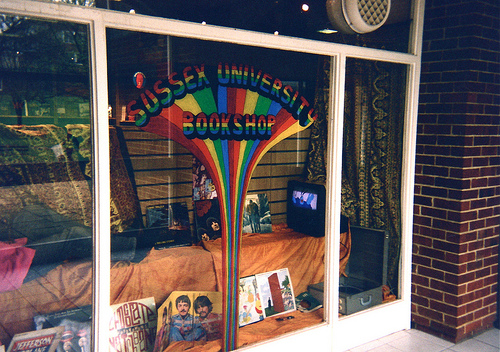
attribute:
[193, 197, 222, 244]
album cover — beatles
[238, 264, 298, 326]
book — open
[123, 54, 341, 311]
wrapping paper — bright pink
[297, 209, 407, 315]
box — grey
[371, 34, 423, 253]
frame — white, wooden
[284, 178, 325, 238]
tv — black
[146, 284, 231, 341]
album — vinyl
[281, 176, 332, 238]
t.v. — on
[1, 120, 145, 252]
rug — oriental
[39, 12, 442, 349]
window — storefront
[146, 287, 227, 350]
photo — beatles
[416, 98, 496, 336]
pillar — red and white, brick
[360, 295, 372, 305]
handle — grey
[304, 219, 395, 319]
record player — old timey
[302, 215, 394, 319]
metal box — open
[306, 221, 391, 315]
suitcase — empty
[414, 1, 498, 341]
brick column — dark red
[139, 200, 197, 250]
cover — album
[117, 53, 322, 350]
design — colorful